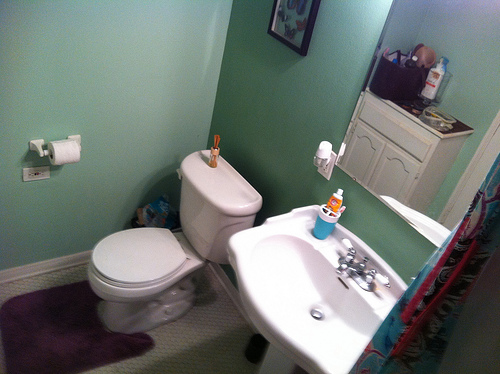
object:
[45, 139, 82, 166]
tissuepaper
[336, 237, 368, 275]
faucet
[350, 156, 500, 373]
curtain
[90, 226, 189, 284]
lid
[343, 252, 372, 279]
tap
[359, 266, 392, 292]
faucet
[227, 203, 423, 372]
sink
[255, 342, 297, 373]
pedestal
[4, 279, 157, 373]
rug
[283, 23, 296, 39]
butterflies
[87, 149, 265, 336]
toilet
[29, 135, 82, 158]
paper holder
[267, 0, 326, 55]
framed art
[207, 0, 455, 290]
wall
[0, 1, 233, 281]
wall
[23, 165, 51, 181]
electrical outlet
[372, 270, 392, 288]
handle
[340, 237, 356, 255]
handle